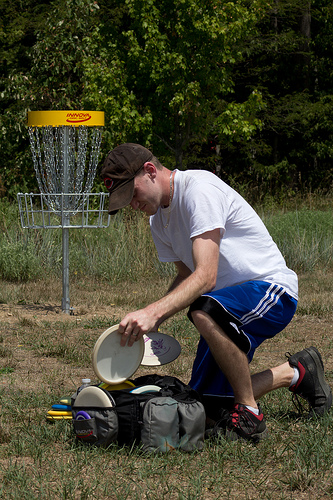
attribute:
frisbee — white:
[92, 323, 152, 389]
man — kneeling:
[89, 133, 321, 437]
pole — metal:
[59, 176, 82, 309]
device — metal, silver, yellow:
[22, 109, 105, 218]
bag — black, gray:
[57, 374, 210, 457]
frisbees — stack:
[76, 384, 114, 408]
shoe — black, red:
[202, 397, 273, 447]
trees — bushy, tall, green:
[6, 3, 332, 130]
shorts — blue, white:
[188, 273, 299, 406]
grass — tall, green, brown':
[78, 215, 157, 275]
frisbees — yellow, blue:
[42, 400, 75, 429]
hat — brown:
[95, 144, 156, 215]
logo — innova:
[72, 425, 99, 441]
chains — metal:
[33, 128, 102, 198]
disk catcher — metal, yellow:
[23, 107, 115, 134]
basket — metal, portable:
[16, 189, 114, 238]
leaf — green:
[86, 64, 94, 72]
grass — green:
[257, 204, 332, 273]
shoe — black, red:
[285, 347, 332, 424]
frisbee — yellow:
[46, 410, 73, 416]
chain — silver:
[26, 124, 57, 211]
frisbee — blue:
[49, 401, 74, 413]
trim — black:
[191, 295, 253, 352]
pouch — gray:
[143, 399, 185, 458]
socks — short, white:
[287, 369, 301, 384]